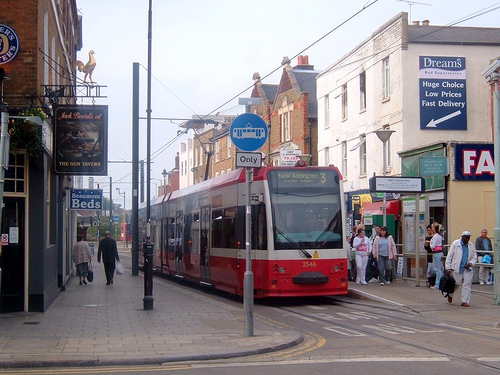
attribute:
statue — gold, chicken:
[71, 50, 96, 83]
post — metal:
[146, 5, 152, 308]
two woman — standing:
[424, 222, 444, 288]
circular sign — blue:
[227, 108, 270, 150]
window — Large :
[265, 166, 344, 248]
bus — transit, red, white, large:
[133, 165, 351, 298]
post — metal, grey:
[244, 167, 254, 334]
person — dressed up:
[95, 228, 120, 290]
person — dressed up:
[75, 232, 94, 287]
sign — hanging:
[50, 100, 114, 178]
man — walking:
[81, 226, 138, 288]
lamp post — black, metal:
[144, 1, 154, 307]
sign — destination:
[232, 110, 271, 167]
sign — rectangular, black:
[46, 100, 110, 176]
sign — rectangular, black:
[70, 181, 109, 209]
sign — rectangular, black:
[363, 170, 430, 198]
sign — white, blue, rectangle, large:
[420, 57, 466, 132]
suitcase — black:
[430, 272, 461, 295]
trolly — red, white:
[127, 156, 355, 318]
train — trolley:
[132, 160, 355, 302]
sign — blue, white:
[196, 100, 309, 209]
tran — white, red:
[123, 164, 343, 301]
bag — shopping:
[113, 259, 128, 281]